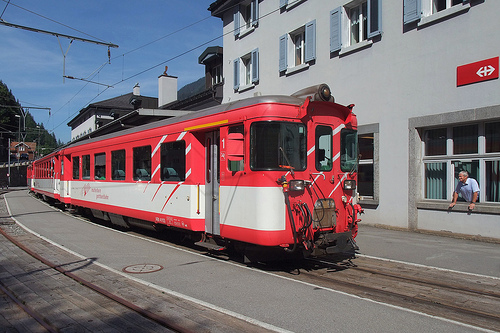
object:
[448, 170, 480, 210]
man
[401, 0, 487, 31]
window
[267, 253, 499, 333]
trolley tracks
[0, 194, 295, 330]
trolley tracks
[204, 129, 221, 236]
doors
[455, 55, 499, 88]
sign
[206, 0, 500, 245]
building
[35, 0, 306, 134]
wires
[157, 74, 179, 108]
chimney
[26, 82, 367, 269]
train